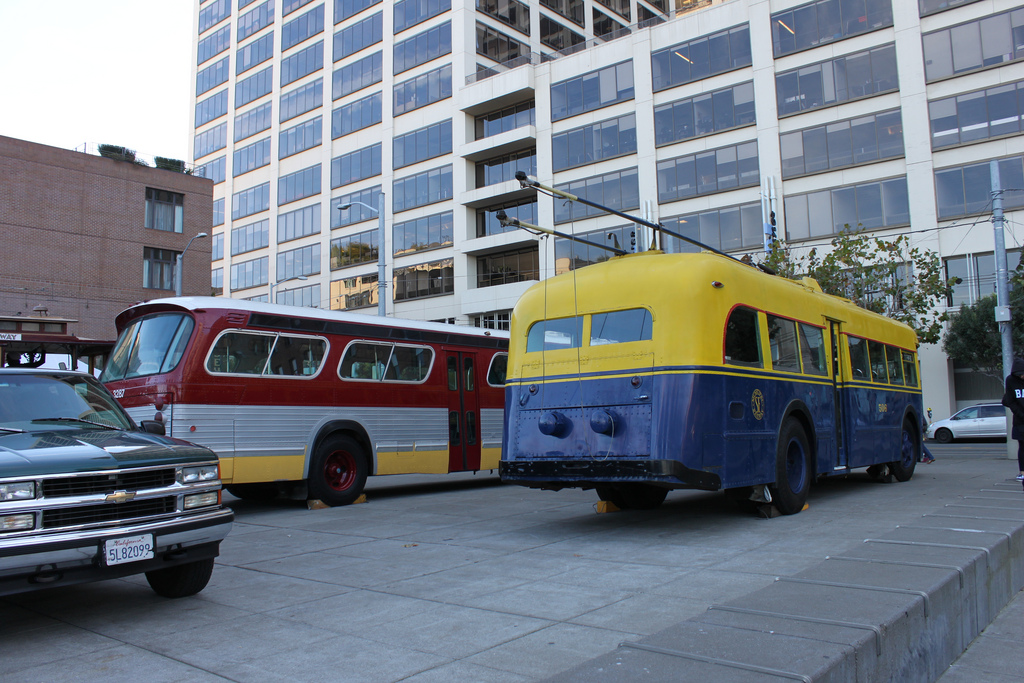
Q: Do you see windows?
A: Yes, there is a window.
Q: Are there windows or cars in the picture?
A: Yes, there is a window.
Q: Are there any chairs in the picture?
A: No, there are no chairs.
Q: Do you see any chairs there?
A: No, there are no chairs.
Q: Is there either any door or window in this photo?
A: Yes, there is a window.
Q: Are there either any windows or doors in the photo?
A: Yes, there is a window.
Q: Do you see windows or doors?
A: Yes, there is a window.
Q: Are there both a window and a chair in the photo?
A: No, there is a window but no chairs.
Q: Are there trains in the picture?
A: No, there are no trains.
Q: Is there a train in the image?
A: No, there are no trains.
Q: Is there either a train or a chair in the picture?
A: No, there are no trains or chairs.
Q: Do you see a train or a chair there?
A: No, there are no trains or chairs.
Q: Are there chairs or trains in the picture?
A: No, there are no trains or chairs.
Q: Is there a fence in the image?
A: No, there are no fences.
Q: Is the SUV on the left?
A: Yes, the SUV is on the left of the image.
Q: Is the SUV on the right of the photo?
A: No, the SUV is on the left of the image.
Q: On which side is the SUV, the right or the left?
A: The SUV is on the left of the image.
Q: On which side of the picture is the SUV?
A: The SUV is on the left of the image.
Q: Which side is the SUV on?
A: The SUV is on the left of the image.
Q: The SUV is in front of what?
A: The SUV is in front of the bus.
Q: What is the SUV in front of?
A: The SUV is in front of the bus.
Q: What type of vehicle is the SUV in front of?
A: The SUV is in front of the bus.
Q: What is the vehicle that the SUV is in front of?
A: The vehicle is a bus.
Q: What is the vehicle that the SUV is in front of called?
A: The vehicle is a bus.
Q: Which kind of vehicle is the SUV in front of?
A: The SUV is in front of the bus.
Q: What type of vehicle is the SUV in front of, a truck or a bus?
A: The SUV is in front of a bus.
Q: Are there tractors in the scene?
A: No, there are no tractors.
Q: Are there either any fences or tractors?
A: No, there are no tractors or fences.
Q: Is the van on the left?
A: No, the van is on the right of the image.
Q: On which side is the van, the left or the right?
A: The van is on the right of the image.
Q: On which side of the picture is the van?
A: The van is on the right of the image.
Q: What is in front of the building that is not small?
A: The van is in front of the building.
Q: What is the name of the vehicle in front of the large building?
A: The vehicle is a van.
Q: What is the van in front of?
A: The van is in front of the building.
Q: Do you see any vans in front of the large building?
A: Yes, there is a van in front of the building.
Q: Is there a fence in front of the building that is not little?
A: No, there is a van in front of the building.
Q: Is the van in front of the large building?
A: Yes, the van is in front of the building.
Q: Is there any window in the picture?
A: Yes, there is a window.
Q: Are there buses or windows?
A: Yes, there is a window.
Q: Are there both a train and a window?
A: No, there is a window but no trains.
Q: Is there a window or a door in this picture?
A: Yes, there is a window.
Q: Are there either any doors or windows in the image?
A: Yes, there is a window.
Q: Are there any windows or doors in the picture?
A: Yes, there is a window.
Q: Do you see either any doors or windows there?
A: Yes, there is a window.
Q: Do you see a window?
A: Yes, there is a window.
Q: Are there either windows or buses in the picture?
A: Yes, there is a window.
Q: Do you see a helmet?
A: No, there are no helmets.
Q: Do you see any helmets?
A: No, there are no helmets.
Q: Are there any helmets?
A: No, there are no helmets.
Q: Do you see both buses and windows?
A: Yes, there are both a window and a bus.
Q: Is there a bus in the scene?
A: Yes, there is a bus.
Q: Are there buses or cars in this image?
A: Yes, there is a bus.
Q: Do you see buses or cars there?
A: Yes, there is a bus.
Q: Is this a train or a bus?
A: This is a bus.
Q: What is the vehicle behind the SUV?
A: The vehicle is a bus.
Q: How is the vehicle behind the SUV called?
A: The vehicle is a bus.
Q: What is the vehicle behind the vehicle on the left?
A: The vehicle is a bus.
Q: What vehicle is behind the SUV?
A: The vehicle is a bus.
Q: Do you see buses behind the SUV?
A: Yes, there is a bus behind the SUV.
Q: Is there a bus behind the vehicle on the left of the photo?
A: Yes, there is a bus behind the SUV.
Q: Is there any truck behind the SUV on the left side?
A: No, there is a bus behind the SUV.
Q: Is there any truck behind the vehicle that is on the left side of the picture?
A: No, there is a bus behind the SUV.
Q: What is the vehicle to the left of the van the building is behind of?
A: The vehicle is a bus.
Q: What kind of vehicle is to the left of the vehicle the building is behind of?
A: The vehicle is a bus.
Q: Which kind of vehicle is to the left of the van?
A: The vehicle is a bus.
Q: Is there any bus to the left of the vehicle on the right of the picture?
A: Yes, there is a bus to the left of the van.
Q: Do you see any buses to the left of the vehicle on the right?
A: Yes, there is a bus to the left of the van.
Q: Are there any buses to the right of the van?
A: No, the bus is to the left of the van.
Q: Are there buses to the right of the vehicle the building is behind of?
A: No, the bus is to the left of the van.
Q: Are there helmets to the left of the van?
A: No, there is a bus to the left of the van.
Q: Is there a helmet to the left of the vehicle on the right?
A: No, there is a bus to the left of the van.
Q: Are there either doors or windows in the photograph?
A: Yes, there is a window.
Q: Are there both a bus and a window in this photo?
A: Yes, there are both a window and a bus.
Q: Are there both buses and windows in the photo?
A: Yes, there are both a window and a bus.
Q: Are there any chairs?
A: No, there are no chairs.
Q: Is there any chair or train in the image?
A: No, there are no chairs or trains.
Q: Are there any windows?
A: Yes, there is a window.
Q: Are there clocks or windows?
A: Yes, there is a window.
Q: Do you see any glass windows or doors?
A: Yes, there is a glass window.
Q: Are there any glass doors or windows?
A: Yes, there is a glass window.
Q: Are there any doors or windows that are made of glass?
A: Yes, the window is made of glass.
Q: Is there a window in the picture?
A: Yes, there is a window.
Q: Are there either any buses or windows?
A: Yes, there is a window.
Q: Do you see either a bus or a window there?
A: Yes, there is a window.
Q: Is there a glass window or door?
A: Yes, there is a glass window.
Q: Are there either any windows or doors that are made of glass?
A: Yes, the window is made of glass.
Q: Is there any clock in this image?
A: No, there are no clocks.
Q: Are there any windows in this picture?
A: Yes, there is a window.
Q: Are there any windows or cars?
A: Yes, there is a window.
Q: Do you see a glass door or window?
A: Yes, there is a glass window.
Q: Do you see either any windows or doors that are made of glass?
A: Yes, the window is made of glass.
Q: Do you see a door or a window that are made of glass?
A: Yes, the window is made of glass.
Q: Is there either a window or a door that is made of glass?
A: Yes, the window is made of glass.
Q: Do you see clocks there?
A: No, there are no clocks.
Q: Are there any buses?
A: Yes, there is a bus.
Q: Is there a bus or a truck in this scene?
A: Yes, there is a bus.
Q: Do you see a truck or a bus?
A: Yes, there is a bus.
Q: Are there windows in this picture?
A: Yes, there is a window.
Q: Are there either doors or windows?
A: Yes, there is a window.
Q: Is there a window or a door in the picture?
A: Yes, there is a window.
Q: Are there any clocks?
A: No, there are no clocks.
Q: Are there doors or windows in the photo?
A: Yes, there is a window.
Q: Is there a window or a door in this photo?
A: Yes, there is a window.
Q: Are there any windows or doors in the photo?
A: Yes, there is a window.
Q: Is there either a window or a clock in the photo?
A: Yes, there is a window.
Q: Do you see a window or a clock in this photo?
A: Yes, there is a window.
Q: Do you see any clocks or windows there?
A: Yes, there is a window.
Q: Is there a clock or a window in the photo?
A: Yes, there is a window.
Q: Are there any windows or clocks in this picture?
A: Yes, there is a window.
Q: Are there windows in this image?
A: Yes, there is a window.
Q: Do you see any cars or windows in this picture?
A: Yes, there is a window.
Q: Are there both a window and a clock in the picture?
A: No, there is a window but no clocks.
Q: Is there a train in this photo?
A: No, there are no trains.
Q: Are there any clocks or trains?
A: No, there are no trains or clocks.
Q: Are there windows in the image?
A: Yes, there is a window.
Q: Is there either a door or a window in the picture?
A: Yes, there is a window.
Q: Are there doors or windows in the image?
A: Yes, there is a window.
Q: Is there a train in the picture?
A: No, there are no trains.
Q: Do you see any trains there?
A: No, there are no trains.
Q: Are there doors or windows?
A: Yes, there is a window.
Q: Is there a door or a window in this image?
A: Yes, there is a window.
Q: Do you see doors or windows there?
A: Yes, there is a window.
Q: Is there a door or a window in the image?
A: Yes, there is a window.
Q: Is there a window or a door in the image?
A: Yes, there is a window.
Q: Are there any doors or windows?
A: Yes, there is a window.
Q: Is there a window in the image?
A: Yes, there is a window.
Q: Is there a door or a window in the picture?
A: Yes, there is a window.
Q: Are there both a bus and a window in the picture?
A: Yes, there are both a window and a bus.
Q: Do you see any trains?
A: No, there are no trains.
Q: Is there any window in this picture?
A: Yes, there is a window.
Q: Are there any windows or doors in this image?
A: Yes, there is a window.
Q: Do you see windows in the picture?
A: Yes, there is a window.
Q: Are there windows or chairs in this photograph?
A: Yes, there is a window.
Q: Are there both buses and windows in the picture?
A: Yes, there are both a window and a bus.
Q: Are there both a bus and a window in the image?
A: Yes, there are both a window and a bus.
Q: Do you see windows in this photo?
A: Yes, there is a window.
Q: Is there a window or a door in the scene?
A: Yes, there is a window.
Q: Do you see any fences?
A: No, there are no fences.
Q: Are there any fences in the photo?
A: No, there are no fences.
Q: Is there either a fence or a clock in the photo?
A: No, there are no fences or clocks.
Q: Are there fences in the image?
A: No, there are no fences.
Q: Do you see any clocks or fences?
A: No, there are no fences or clocks.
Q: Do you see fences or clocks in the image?
A: No, there are no fences or clocks.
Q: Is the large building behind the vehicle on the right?
A: Yes, the building is behind the van.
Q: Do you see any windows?
A: Yes, there is a window.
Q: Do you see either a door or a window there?
A: Yes, there is a window.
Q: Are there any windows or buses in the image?
A: Yes, there is a window.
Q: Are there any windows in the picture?
A: Yes, there is a window.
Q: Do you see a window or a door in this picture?
A: Yes, there is a window.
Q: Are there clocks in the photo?
A: No, there are no clocks.